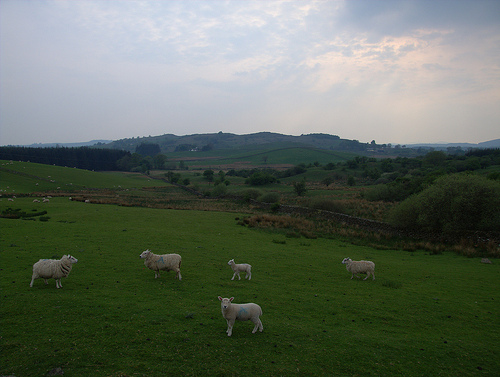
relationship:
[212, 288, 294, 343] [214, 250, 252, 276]
sheep looking at or sheep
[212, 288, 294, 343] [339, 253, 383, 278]
sheep looking at or sheep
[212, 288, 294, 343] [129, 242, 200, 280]
sheep looking at or sheep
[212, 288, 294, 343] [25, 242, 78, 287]
sheep looking at or sheep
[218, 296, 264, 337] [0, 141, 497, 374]
sheep in field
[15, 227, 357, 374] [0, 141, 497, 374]
sheep walking in field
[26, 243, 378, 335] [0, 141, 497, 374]
sheep standing in field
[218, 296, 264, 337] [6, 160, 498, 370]
sheep on grass